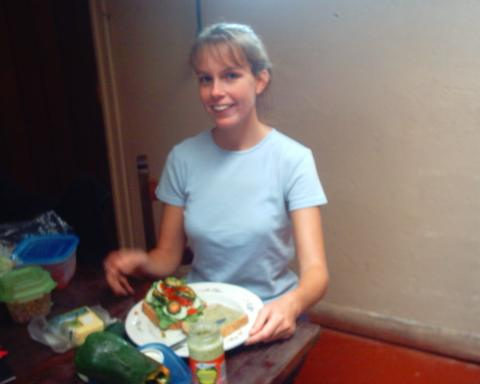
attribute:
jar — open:
[186, 320, 227, 382]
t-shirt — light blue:
[169, 150, 330, 297]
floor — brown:
[315, 333, 478, 379]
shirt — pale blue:
[151, 123, 325, 321]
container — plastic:
[9, 231, 82, 290]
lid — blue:
[10, 229, 79, 265]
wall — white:
[302, 35, 458, 251]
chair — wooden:
[134, 153, 190, 269]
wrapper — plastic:
[0, 204, 76, 245]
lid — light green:
[0, 264, 58, 303]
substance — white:
[190, 340, 229, 377]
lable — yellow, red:
[187, 355, 228, 383]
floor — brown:
[123, 266, 472, 382]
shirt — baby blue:
[157, 129, 329, 340]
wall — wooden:
[2, 4, 122, 274]